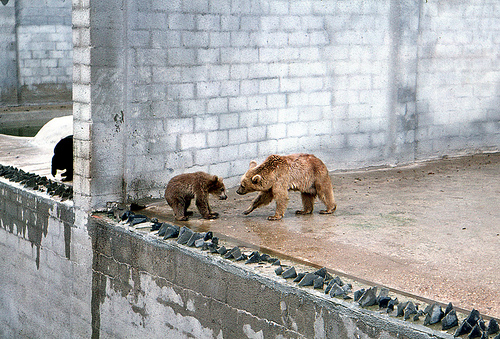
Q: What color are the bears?
A: Brown.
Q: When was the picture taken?
A: Daytime.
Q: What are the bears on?
A: Dirt.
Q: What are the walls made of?
A: Stone.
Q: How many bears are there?
A: Two.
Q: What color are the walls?
A: Gray.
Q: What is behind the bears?
A: The wall.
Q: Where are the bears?
A: In front of the wall.